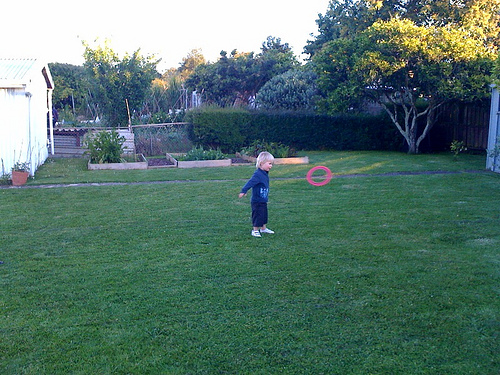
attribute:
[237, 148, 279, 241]
boy — little, young, playing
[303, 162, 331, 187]
disc — red, in air, pink, airborne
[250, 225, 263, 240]
shoe — white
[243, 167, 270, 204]
shirt — blue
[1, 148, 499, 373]
grass — green, big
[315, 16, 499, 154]
tree — medium-sized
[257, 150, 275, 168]
hair — blonde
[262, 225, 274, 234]
shoe — white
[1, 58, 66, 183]
shed — white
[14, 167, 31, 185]
pot — red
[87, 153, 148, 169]
planter — reddish, wooden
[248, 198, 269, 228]
shorts — blue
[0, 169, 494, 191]
sidewalk — grey